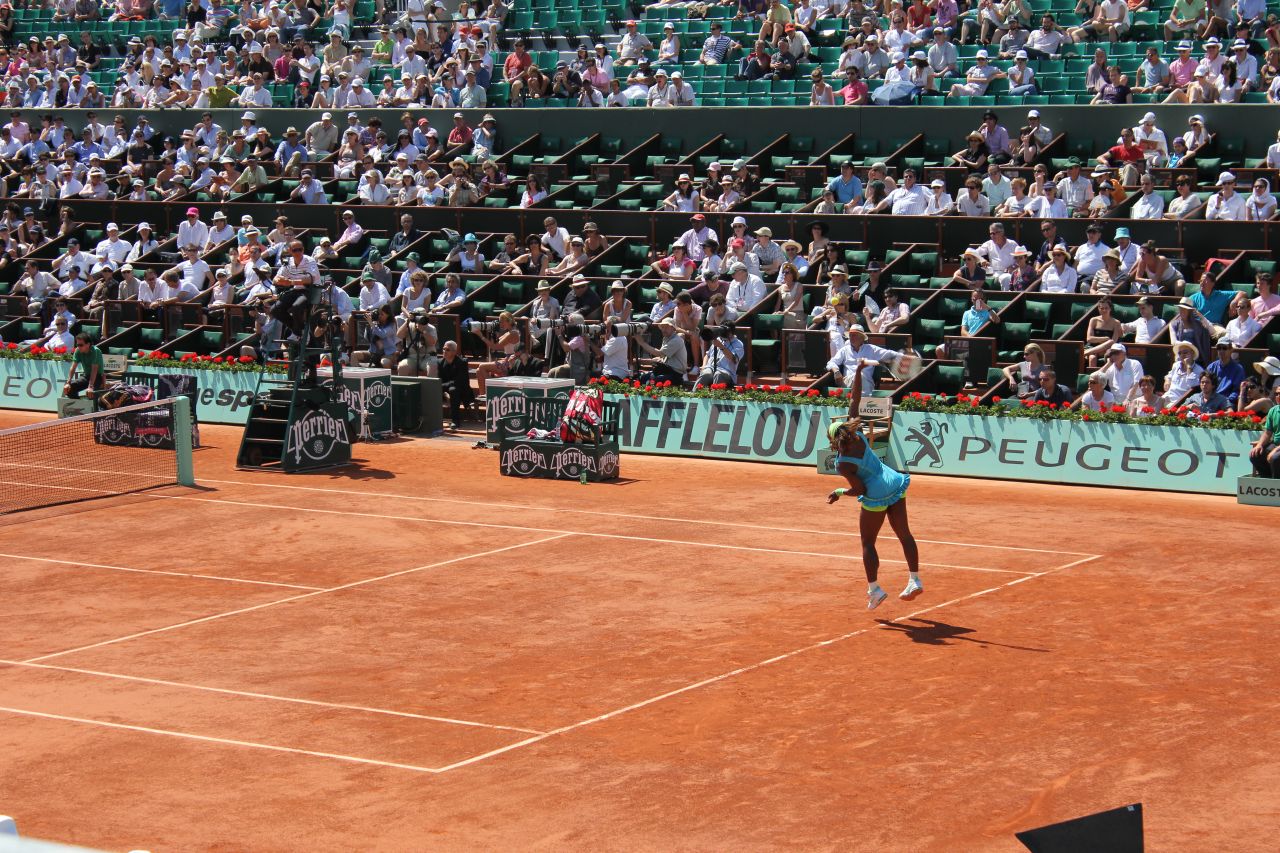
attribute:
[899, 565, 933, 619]
shoe — white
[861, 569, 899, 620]
shoe — white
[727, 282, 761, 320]
shirt — white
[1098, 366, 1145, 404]
shirt — white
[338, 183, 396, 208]
shirt — white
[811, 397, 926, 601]
player — female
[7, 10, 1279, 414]
spectators — crowd, tennis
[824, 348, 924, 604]
player — tennis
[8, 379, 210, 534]
tennis net — mounted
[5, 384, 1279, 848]
tennis court — brown, white